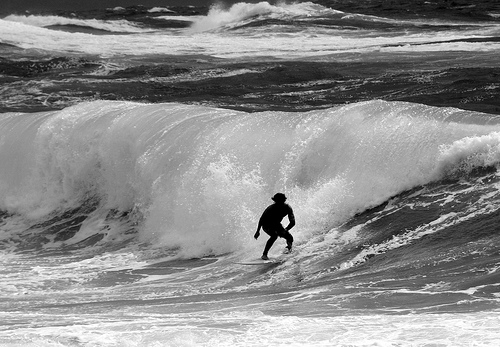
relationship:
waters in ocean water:
[2, 99, 492, 261] [3, 3, 495, 345]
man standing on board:
[254, 192, 296, 260] [228, 252, 284, 271]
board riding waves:
[228, 252, 284, 271] [15, 6, 445, 277]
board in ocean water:
[233, 248, 293, 265] [3, 3, 495, 345]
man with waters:
[254, 192, 296, 260] [2, 99, 492, 261]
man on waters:
[254, 192, 296, 260] [2, 99, 492, 261]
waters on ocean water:
[2, 99, 492, 261] [3, 3, 495, 345]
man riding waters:
[254, 192, 296, 260] [2, 99, 492, 261]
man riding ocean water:
[254, 192, 296, 260] [3, 3, 495, 345]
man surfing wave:
[243, 192, 303, 279] [325, 93, 470, 238]